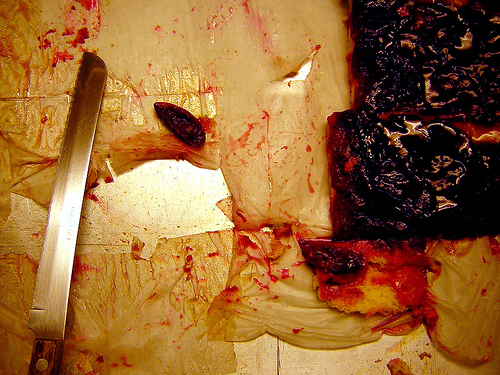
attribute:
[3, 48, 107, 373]
knife — large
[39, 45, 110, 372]
bread knife — large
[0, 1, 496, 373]
table — metal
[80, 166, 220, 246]
table — gray, metal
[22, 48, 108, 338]
blade — metal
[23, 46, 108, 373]
knife — big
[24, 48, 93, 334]
blade edge — serrated